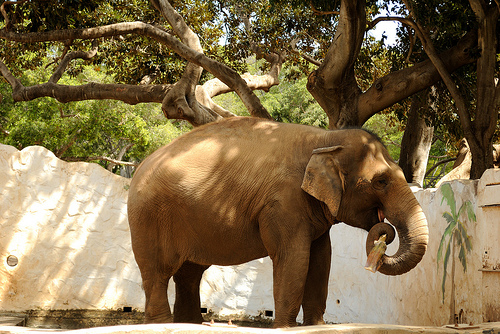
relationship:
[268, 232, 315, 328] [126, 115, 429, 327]
leg of elephant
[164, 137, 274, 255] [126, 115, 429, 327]
stomach of elephant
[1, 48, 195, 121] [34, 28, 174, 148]
branch of tree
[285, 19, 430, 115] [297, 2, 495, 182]
branch of tree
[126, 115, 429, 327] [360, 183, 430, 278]
elephant feeding trunk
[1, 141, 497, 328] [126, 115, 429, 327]
barrier around elephant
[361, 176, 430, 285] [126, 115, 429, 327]
trunk of an elephant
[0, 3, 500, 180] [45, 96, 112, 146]
tree with leaves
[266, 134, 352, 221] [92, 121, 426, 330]
ear of an elephant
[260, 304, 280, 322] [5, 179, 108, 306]
hole in wall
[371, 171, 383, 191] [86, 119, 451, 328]
eye of elephant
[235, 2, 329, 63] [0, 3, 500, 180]
leaves on tree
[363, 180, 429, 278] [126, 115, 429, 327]
trunk of elephant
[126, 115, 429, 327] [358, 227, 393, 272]
elephant eating branch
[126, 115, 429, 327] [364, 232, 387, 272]
elephant eating branch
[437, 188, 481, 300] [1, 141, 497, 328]
painting on barrier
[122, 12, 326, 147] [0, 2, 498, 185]
branch of tree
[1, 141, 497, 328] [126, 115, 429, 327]
barrier fencing in elephant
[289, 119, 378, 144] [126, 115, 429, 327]
hair on elephant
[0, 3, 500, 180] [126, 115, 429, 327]
tree outside elephant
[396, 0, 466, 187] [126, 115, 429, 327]
tree outside elephant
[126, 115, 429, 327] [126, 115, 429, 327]
elephant of elephant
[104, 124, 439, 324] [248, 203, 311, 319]
elephant has leg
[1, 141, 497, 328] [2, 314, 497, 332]
barrier has floor